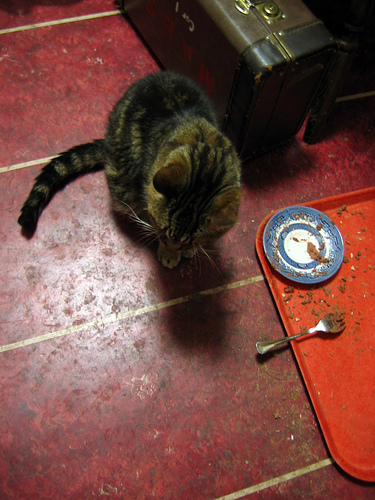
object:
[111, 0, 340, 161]
suitcase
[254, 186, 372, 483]
orange tray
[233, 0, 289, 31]
lock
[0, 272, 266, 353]
lines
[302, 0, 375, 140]
chair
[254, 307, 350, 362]
fork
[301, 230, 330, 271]
saucer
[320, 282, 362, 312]
crumbs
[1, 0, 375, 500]
floor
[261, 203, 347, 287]
plate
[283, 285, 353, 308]
cat food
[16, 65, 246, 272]
cat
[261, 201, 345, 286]
blue decal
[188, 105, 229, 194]
stripes